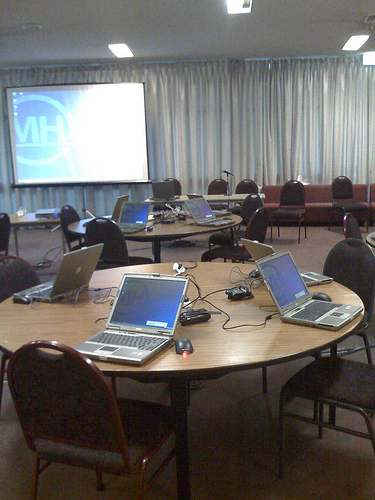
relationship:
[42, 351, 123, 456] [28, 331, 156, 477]
padding on chair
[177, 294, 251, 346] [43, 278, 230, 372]
mouse on table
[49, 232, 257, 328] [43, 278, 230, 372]
laptops on table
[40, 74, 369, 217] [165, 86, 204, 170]
wall of curtain